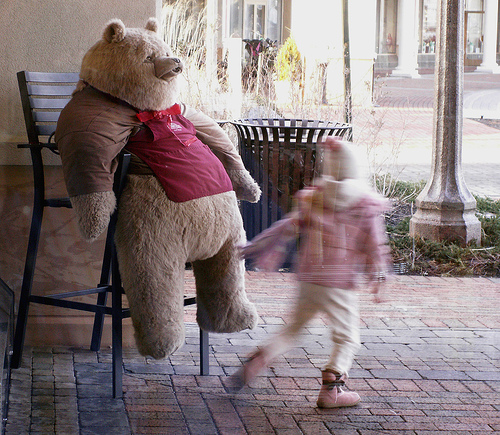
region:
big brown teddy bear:
[59, 19, 266, 360]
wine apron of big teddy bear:
[128, 108, 235, 208]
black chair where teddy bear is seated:
[7, 68, 210, 403]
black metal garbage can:
[231, 115, 357, 277]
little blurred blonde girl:
[225, 139, 397, 410]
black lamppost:
[410, 3, 487, 248]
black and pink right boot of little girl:
[317, 366, 361, 410]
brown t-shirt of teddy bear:
[56, 80, 252, 197]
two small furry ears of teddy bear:
[101, 19, 165, 44]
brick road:
[7, 255, 497, 431]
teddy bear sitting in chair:
[50, 4, 275, 350]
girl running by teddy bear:
[222, 126, 389, 411]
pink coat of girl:
[231, 183, 400, 280]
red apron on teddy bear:
[130, 106, 235, 205]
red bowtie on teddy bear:
[134, 99, 196, 123]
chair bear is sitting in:
[12, 65, 214, 381]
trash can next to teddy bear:
[229, 113, 367, 273]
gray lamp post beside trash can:
[399, 35, 481, 250]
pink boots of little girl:
[228, 343, 383, 408]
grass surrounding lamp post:
[372, 177, 497, 253]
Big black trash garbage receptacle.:
[231, 115, 358, 265]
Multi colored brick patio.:
[399, 287, 489, 421]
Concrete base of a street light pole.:
[411, 10, 482, 255]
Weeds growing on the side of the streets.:
[381, 174, 496, 281]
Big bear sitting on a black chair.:
[55, 15, 262, 360]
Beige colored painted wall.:
[12, 1, 151, 17]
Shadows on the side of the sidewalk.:
[384, 110, 498, 180]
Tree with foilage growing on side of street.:
[274, 34, 323, 124]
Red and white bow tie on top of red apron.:
[134, 104, 197, 125]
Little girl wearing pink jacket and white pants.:
[225, 132, 395, 411]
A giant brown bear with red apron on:
[50, 15, 264, 360]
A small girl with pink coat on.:
[236, 130, 391, 405]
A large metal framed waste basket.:
[226, 118, 350, 270]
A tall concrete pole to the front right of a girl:
[405, 0, 484, 243]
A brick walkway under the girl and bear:
[0, 264, 499, 432]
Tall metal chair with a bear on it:
[9, 71, 211, 397]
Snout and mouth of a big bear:
[153, 56, 185, 78]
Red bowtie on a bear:
[131, 103, 182, 123]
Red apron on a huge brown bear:
[126, 103, 233, 202]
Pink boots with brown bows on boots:
[226, 355, 361, 410]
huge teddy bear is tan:
[105, 55, 202, 251]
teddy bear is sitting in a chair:
[45, 166, 179, 251]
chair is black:
[36, 115, 59, 230]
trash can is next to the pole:
[246, 121, 299, 223]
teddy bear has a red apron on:
[140, 105, 191, 196]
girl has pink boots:
[323, 370, 373, 410]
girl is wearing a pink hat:
[322, 143, 372, 174]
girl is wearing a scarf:
[250, 217, 286, 249]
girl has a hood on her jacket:
[312, 167, 375, 208]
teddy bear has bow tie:
[134, 96, 181, 116]